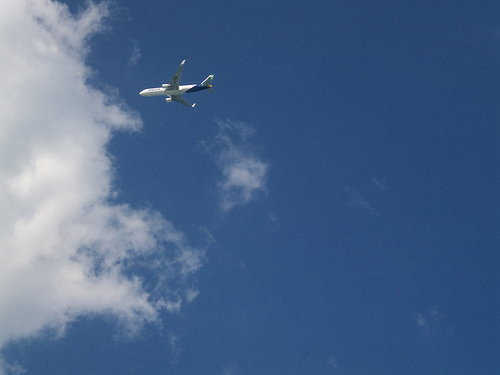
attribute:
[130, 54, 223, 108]
plane — flying, white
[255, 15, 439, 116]
sky — blue, cloudy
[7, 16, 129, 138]
clouds — white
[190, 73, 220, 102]
tail — blue, light blue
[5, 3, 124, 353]
cloud — large, denser, big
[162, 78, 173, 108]
engines — parallel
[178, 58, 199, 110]
winglets — white, bent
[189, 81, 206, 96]
blue — diagonal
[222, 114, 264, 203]
little — wispy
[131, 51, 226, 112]
plane — sleek, minimal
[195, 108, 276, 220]
cloud — little